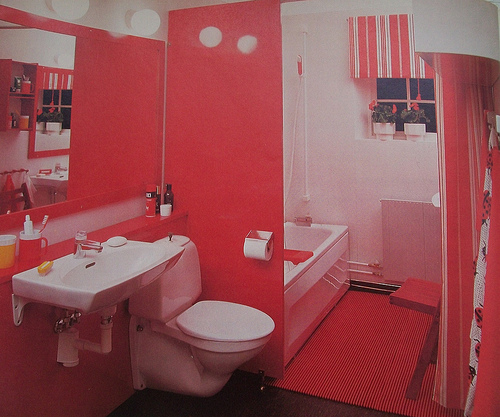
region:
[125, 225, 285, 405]
A white toilet in the foreground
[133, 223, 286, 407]
The toilet seat is down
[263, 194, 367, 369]
A tub in the background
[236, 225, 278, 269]
A roll of toilet paper in the foreground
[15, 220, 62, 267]
A red cup in the foreground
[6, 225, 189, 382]
A bathroom sink in the foreground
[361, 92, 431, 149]
Two flower pots in the background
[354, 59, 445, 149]
A window in the background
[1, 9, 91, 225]
A bathroom mirror in the foreground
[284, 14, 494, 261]
The background wall is white in color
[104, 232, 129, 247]
Soap on a basin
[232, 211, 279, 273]
Toilet paper and dispenser on the wall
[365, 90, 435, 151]
Two flowerpots in a window box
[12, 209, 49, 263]
Toothbrush and toothpaste in a cup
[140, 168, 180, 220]
Shaving creme, mouthwash and other toiletries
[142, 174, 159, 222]
Shaving cream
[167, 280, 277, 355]
Toilet seat cover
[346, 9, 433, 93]
Striped shade in a window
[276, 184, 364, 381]
A white bathtub and red flooring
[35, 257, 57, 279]
A scrub brush on a basin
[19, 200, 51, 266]
a pink and white plastic cup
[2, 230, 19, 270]
a yellow and white plastic cup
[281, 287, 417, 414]
a pink rug on the floor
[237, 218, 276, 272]
a roll of toilet paper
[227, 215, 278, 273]
a roll of toilet paper on a holder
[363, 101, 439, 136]
two small plants on a window sill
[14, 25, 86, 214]
a mirror hanging on a wall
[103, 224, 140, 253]
a bar of soap on a sink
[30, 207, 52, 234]
a pink toothbrush in a cup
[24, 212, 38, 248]
a tube of toothpaste in a cup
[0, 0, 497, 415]
a bathroom with red and white decor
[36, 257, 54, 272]
a nail cleaning brush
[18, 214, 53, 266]
a cup holding toothpaste toothbrush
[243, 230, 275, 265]
a roll of toilet paper on the wall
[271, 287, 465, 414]
a red bath mat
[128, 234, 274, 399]
a white porcelain commode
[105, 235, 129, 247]
a white bar of soap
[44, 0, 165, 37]
a row of decorative lighting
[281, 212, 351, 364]
a white porcelain bathtub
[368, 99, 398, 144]
a plant in the window sill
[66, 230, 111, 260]
silver faucet on sink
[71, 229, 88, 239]
white knob on top of sink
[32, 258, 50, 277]
yellow container by sink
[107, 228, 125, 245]
white bar of soap on sink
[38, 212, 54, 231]
red toothbrush in cup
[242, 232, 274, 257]
white toilet paper on wall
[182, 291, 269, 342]
white toilet lid in bathroom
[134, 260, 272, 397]
white base to toilet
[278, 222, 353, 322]
white bathtub in corner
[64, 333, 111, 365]
white piping of sink